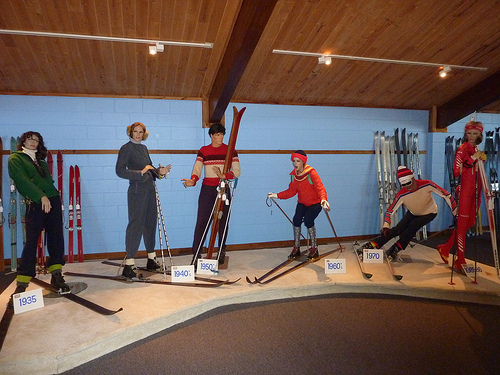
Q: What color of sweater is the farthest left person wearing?
A: Green.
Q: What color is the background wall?
A: Blue.